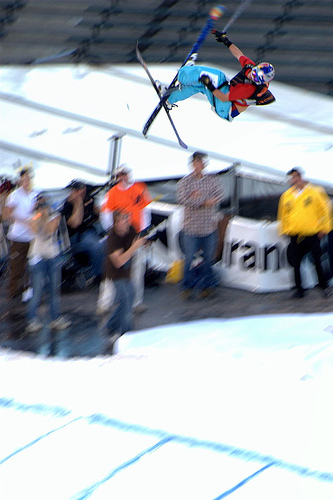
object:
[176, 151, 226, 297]
man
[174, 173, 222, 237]
shirt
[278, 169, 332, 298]
man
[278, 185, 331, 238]
jacket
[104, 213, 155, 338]
man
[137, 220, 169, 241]
camera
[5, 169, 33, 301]
man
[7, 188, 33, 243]
shirt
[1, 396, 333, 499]
lines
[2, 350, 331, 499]
snow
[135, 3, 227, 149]
ski's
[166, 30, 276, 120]
man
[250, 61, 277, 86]
helmet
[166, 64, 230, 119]
pants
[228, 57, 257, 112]
shirt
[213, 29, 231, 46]
glove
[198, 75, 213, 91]
glove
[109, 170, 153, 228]
man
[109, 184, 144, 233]
shirt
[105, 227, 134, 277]
shirt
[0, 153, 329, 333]
crowd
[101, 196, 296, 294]
sign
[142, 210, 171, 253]
logo